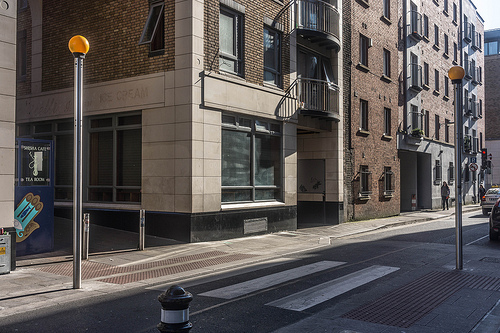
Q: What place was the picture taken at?
A: It was taken at the street.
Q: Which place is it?
A: It is a street.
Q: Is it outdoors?
A: Yes, it is outdoors.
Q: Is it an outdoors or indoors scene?
A: It is outdoors.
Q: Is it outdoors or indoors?
A: It is outdoors.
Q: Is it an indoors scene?
A: No, it is outdoors.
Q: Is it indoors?
A: No, it is outdoors.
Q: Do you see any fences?
A: No, there are no fences.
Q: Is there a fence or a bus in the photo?
A: No, there are no fences or buses.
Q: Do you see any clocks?
A: No, there are no clocks.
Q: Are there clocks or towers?
A: No, there are no clocks or towers.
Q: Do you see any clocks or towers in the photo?
A: No, there are no clocks or towers.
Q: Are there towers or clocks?
A: No, there are no clocks or towers.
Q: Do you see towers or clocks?
A: No, there are no clocks or towers.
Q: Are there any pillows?
A: No, there are no pillows.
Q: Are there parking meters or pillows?
A: No, there are no pillows or parking meters.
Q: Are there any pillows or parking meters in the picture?
A: No, there are no pillows or parking meters.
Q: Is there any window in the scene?
A: Yes, there is a window.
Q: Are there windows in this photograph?
A: Yes, there is a window.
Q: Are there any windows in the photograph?
A: Yes, there is a window.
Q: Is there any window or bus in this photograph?
A: Yes, there is a window.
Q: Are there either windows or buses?
A: Yes, there is a window.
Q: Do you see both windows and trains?
A: No, there is a window but no trains.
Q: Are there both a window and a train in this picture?
A: No, there is a window but no trains.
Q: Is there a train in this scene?
A: No, there are no trains.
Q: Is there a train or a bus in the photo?
A: No, there are no trains or buses.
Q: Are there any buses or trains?
A: No, there are no trains or buses.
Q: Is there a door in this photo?
A: Yes, there is a door.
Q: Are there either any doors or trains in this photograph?
A: Yes, there is a door.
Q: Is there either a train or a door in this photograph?
A: Yes, there is a door.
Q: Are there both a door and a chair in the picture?
A: No, there is a door but no chairs.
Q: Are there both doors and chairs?
A: No, there is a door but no chairs.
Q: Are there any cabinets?
A: No, there are no cabinets.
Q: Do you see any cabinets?
A: No, there are no cabinets.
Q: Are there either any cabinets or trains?
A: No, there are no cabinets or trains.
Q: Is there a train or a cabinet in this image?
A: No, there are no cabinets or trains.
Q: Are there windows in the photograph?
A: Yes, there is a window.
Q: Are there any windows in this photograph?
A: Yes, there is a window.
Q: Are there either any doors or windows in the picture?
A: Yes, there is a window.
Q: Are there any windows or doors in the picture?
A: Yes, there is a window.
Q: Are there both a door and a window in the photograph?
A: Yes, there are both a window and a door.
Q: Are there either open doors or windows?
A: Yes, there is an open window.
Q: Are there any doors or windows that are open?
A: Yes, the window is open.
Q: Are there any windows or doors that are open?
A: Yes, the window is open.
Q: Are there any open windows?
A: Yes, there is an open window.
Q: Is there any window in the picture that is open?
A: Yes, there is a window that is open.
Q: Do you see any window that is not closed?
A: Yes, there is a open window.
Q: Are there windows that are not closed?
A: Yes, there is a open window.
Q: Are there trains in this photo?
A: No, there are no trains.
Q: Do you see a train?
A: No, there are no trains.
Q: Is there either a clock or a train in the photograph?
A: No, there are no trains or clocks.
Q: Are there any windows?
A: Yes, there is a window.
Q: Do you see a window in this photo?
A: Yes, there is a window.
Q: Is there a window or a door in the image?
A: Yes, there is a window.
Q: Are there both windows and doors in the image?
A: Yes, there are both a window and a door.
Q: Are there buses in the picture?
A: No, there are no buses.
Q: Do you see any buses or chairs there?
A: No, there are no buses or chairs.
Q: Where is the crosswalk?
A: The crosswalk is on the street.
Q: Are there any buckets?
A: No, there are no buckets.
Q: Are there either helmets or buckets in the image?
A: No, there are no buckets or helmets.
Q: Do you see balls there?
A: Yes, there is a ball.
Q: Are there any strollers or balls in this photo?
A: Yes, there is a ball.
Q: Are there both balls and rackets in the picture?
A: No, there is a ball but no rackets.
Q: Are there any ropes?
A: No, there are no ropes.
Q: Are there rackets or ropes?
A: No, there are no ropes or rackets.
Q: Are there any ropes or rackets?
A: No, there are no ropes or rackets.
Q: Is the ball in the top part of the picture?
A: Yes, the ball is in the top of the image.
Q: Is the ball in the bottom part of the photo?
A: No, the ball is in the top of the image.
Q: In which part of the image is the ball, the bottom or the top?
A: The ball is in the top of the image.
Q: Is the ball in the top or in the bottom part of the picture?
A: The ball is in the top of the image.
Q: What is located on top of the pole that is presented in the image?
A: The ball is on top of the pole.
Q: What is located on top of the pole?
A: The ball is on top of the pole.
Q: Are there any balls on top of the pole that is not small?
A: Yes, there is a ball on top of the pole.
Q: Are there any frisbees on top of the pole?
A: No, there is a ball on top of the pole.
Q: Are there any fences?
A: No, there are no fences.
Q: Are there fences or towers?
A: No, there are no fences or towers.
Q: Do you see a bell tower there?
A: No, there are no bell towers.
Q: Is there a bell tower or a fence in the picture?
A: No, there are no bell towers or fences.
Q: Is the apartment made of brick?
A: Yes, the apartment is made of brick.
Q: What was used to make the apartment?
A: The apartment is made of brick.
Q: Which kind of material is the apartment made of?
A: The apartment is made of brick.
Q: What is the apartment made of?
A: The apartment is made of brick.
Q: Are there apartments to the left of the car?
A: Yes, there is an apartment to the left of the car.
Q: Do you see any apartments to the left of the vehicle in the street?
A: Yes, there is an apartment to the left of the car.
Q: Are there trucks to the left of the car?
A: No, there is an apartment to the left of the car.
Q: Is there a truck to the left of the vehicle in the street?
A: No, there is an apartment to the left of the car.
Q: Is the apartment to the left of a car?
A: Yes, the apartment is to the left of a car.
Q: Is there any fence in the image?
A: No, there are no fences.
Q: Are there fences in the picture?
A: No, there are no fences.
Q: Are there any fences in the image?
A: No, there are no fences.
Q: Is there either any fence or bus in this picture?
A: No, there are no fences or buses.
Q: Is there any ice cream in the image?
A: Yes, there is ice cream.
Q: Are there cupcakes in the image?
A: No, there are no cupcakes.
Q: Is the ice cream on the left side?
A: Yes, the ice cream is on the left of the image.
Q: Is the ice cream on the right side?
A: No, the ice cream is on the left of the image.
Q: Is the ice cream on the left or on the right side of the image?
A: The ice cream is on the left of the image.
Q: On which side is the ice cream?
A: The ice cream is on the left of the image.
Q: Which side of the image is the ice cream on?
A: The ice cream is on the left of the image.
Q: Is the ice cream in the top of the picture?
A: Yes, the ice cream is in the top of the image.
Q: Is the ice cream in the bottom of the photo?
A: No, the ice cream is in the top of the image.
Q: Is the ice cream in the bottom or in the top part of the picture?
A: The ice cream is in the top of the image.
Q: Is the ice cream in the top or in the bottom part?
A: The ice cream is in the top of the image.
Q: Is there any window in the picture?
A: Yes, there is a window.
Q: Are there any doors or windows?
A: Yes, there is a window.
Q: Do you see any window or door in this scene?
A: Yes, there is a window.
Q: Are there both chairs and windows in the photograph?
A: No, there is a window but no chairs.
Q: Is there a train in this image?
A: No, there are no trains.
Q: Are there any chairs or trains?
A: No, there are no trains or chairs.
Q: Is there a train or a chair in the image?
A: No, there are no trains or chairs.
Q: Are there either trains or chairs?
A: No, there are no trains or chairs.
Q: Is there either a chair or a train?
A: No, there are no trains or chairs.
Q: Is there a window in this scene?
A: Yes, there is a window.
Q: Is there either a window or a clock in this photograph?
A: Yes, there is a window.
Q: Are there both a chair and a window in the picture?
A: No, there is a window but no chairs.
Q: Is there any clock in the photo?
A: No, there are no clocks.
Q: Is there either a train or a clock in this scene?
A: No, there are no clocks or trains.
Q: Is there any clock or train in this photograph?
A: No, there are no clocks or trains.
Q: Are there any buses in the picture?
A: No, there are no buses.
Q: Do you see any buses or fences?
A: No, there are no buses or fences.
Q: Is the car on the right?
A: Yes, the car is on the right of the image.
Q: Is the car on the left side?
A: No, the car is on the right of the image.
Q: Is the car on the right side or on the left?
A: The car is on the right of the image.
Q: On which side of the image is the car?
A: The car is on the right of the image.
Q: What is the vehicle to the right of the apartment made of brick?
A: The vehicle is a car.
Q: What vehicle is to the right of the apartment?
A: The vehicle is a car.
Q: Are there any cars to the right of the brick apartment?
A: Yes, there is a car to the right of the apartment.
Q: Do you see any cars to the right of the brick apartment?
A: Yes, there is a car to the right of the apartment.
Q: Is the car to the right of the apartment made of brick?
A: Yes, the car is to the right of the apartment.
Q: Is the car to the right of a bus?
A: No, the car is to the right of the apartment.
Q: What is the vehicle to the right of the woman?
A: The vehicle is a car.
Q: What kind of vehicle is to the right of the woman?
A: The vehicle is a car.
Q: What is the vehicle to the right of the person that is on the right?
A: The vehicle is a car.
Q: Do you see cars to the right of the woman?
A: Yes, there is a car to the right of the woman.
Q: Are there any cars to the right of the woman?
A: Yes, there is a car to the right of the woman.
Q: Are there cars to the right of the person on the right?
A: Yes, there is a car to the right of the woman.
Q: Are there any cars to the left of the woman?
A: No, the car is to the right of the woman.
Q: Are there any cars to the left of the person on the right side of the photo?
A: No, the car is to the right of the woman.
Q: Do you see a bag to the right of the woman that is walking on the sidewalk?
A: No, there is a car to the right of the woman.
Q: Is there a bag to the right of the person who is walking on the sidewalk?
A: No, there is a car to the right of the woman.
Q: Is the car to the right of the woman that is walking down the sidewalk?
A: Yes, the car is to the right of the woman.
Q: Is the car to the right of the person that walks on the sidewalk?
A: Yes, the car is to the right of the woman.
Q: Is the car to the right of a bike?
A: No, the car is to the right of the woman.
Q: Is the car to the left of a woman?
A: No, the car is to the right of a woman.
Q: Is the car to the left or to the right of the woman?
A: The car is to the right of the woman.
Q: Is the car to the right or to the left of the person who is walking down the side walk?
A: The car is to the right of the woman.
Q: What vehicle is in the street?
A: The vehicle is a car.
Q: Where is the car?
A: The car is in the street.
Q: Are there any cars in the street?
A: Yes, there is a car in the street.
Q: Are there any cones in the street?
A: No, there is a car in the street.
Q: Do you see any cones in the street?
A: No, there is a car in the street.